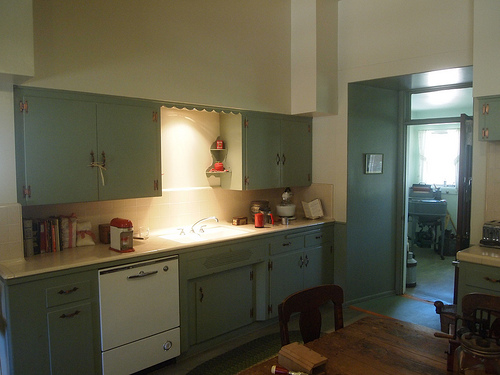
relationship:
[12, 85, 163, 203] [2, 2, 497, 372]
cabinet in kitchen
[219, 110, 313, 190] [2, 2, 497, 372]
cabinet in kitchen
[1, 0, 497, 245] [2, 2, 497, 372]
wall in kitchen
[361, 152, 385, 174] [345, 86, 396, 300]
photo on wall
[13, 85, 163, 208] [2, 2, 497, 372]
cabinet in kitchen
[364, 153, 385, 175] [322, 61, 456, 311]
photo on wall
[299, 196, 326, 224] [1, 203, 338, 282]
book on counter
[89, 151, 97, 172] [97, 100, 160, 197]
handle on door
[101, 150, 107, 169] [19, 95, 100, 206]
handle on cabinet door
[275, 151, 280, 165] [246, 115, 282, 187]
handle on door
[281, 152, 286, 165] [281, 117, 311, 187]
handle on door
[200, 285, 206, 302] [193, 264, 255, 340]
handle on door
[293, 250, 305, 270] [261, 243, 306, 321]
handle on door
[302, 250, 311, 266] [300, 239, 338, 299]
handle on door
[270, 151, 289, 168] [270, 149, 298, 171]
handle on door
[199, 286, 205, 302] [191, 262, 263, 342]
handle on cabinet door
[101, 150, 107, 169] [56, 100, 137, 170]
handle on door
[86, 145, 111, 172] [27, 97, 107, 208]
handle on cabinet door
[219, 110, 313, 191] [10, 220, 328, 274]
cabinet above counter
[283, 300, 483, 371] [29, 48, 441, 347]
table above kitchen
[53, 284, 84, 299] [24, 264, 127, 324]
handle above drawer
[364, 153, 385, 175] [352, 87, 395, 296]
photo on wall